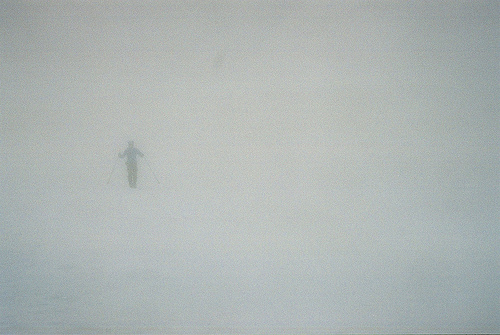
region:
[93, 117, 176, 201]
this is a person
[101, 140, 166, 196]
a set of poles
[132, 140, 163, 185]
a right ski pole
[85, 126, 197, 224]
a person holding ski poles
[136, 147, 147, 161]
this is a right arm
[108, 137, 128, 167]
this is a left arm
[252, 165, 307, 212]
a blizzard snow storm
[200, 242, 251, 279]
a blizzard snow storm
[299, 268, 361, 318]
a blizzard snow storm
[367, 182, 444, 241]
a blizzard snow storm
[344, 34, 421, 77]
a blizzard snow storm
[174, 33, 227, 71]
a blizzard snow storm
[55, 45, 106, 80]
a blizzard snow storm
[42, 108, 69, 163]
a blizzard snow storm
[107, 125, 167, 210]
person standing in the snow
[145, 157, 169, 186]
ski pole in hand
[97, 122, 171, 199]
person standing in the snow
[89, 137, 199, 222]
person standing in the snow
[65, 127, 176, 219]
person standing in the snow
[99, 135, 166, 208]
person standing in the snow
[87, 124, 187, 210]
person standing in the snow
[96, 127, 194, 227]
person standing in the snow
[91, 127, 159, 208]
person standing in the snow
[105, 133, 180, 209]
person standing in the snow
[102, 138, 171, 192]
person on the snow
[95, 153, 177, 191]
a pair of ski poles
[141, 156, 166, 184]
ski pole sticking in the snow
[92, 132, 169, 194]
a person skiing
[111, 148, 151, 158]
arms are lifted up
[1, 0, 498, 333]
snow on the ground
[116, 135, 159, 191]
silhouette of a person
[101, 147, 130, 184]
hand holding the ski pole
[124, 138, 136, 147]
person's head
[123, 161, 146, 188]
a pair of legs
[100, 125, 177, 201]
a guy that is skiing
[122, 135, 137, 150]
the head of a man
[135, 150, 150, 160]
the left arm of a man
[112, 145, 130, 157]
the right arm of a man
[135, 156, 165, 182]
the left ski stick of a man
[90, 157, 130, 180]
the right ski stick of a man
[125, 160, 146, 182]
the legs of a man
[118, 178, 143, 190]
the shoes of a man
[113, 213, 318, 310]
a big patch of snow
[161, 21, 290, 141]
a big flurry of snow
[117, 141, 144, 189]
a person in a field on a foggy day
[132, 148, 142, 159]
a person's outstretched arm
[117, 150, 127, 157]
a person's outstretched arm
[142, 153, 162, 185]
a ski pole in a person's hand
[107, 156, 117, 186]
a ski pole in a person's hand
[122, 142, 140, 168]
a dark jacket on a person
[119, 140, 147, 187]
blurry person through the snow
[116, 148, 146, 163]
open arms of blurry person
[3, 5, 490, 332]
blurry white mist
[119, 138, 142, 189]
person wearing black outfit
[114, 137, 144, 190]
person standing between mist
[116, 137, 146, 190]
person with open arms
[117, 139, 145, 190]
person on white scene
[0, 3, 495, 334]
blurry picture with person standing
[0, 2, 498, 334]
blurry image with person standing with open arms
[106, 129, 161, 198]
a man is on the snow